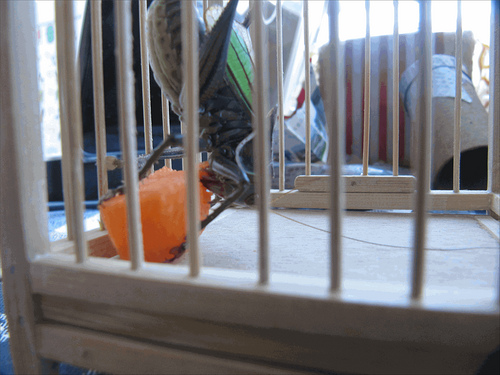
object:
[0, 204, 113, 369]
floor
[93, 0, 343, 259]
bug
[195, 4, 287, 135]
wing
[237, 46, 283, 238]
rod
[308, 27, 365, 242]
rod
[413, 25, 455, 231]
rod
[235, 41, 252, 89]
green wing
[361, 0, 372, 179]
rod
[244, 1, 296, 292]
rod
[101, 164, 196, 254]
food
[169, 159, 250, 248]
leg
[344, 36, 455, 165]
strips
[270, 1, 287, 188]
rod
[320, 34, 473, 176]
chair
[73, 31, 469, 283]
bars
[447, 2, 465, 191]
wooden rod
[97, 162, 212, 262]
cube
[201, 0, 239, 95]
legs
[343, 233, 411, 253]
long antenna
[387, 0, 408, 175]
wooden rod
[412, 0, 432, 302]
rod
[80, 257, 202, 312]
wooden rod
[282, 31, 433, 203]
door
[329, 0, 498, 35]
window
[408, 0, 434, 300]
rod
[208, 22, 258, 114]
wing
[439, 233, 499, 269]
antennae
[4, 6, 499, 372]
cage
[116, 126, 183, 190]
leg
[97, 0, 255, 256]
insect